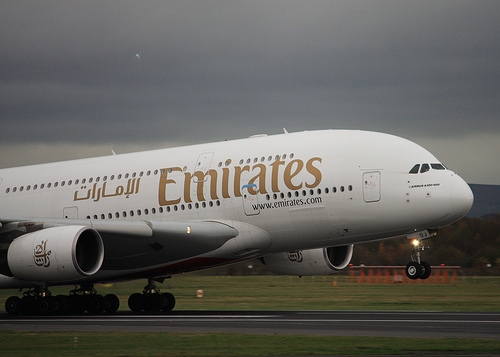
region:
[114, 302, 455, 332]
The ground is made of asphalt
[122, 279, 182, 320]
The wheels on the airplane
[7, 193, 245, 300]
The wing of the airplane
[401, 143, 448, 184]
The window to the cockpit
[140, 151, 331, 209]
The logo on the airplane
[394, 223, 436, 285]
The front wheel of the airplane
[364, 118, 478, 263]
The nose of the airplane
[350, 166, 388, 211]
The door of the airplane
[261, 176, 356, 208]
The side windows on the airplane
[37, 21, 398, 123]
The sky is the color gray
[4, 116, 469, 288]
gold and white plane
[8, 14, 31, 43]
white clouds in blue sky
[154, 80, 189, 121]
white clouds in blue sky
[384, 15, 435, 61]
white clouds in blue sky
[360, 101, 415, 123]
white clouds in blue sky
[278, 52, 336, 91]
white clouds in blue sky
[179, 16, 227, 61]
white clouds in blue sky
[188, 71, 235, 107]
white clouds in blue sky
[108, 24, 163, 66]
white clouds in blue sky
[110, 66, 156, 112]
white clouds in blue sky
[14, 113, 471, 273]
white and gold airplane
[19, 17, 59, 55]
white clouds in blue sky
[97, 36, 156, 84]
white clouds in blue sky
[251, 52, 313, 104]
white clouds in blue sky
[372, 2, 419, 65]
white clouds in blue sky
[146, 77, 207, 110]
white clouds in blue sky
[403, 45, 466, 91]
white clouds in blue sky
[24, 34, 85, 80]
white clouds in blue sky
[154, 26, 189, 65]
white clouds in blue sky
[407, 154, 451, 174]
windshield of a plane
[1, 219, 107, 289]
engine of a plane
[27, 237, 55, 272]
logo painted on plane engine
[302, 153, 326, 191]
letter painted on side of plane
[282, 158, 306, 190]
letter painted on side of plane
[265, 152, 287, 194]
letter painted on side of plane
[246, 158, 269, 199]
letter painted on side of plane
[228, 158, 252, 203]
letter painted on side of plane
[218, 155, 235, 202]
letter painted on side of plane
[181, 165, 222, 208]
letter painted on side of plane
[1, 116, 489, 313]
airplane about to take off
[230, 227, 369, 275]
turbines of an airplane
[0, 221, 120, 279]
turbines of an airplane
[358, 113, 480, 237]
cockpit of an airplane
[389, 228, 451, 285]
front wheels of an airplane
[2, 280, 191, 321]
rear wheels of an airplane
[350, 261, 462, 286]
a bunch of leading cones on floor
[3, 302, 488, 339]
landing ground for airplane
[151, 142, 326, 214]
name of the airline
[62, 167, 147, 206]
characters printed on body of aircraft